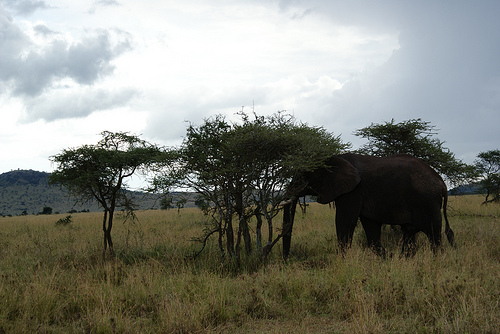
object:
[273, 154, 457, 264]
elephant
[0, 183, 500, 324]
plains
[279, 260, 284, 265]
food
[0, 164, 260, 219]
hill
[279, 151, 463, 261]
alone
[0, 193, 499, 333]
grass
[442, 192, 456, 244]
tail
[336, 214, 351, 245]
leg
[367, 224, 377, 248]
leg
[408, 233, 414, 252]
leg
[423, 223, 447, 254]
leg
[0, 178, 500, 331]
ground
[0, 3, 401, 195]
bad clouds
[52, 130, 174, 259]
tree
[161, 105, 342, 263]
tree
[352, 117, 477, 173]
tree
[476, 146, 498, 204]
tree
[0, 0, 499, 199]
sky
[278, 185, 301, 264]
trunk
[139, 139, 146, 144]
leaf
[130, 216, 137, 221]
leaf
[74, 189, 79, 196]
leaf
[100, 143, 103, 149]
leaf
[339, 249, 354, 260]
feet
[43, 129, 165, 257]
bushes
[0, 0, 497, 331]
africa